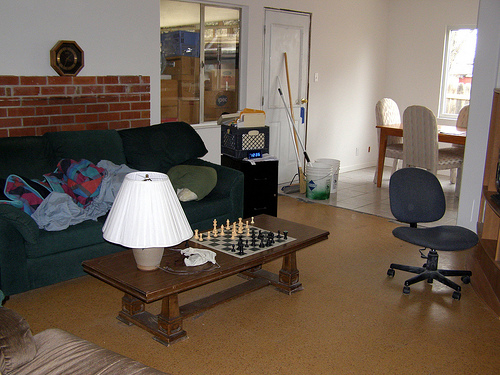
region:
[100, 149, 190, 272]
A lamp on the table.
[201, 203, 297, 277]
A chess game on the table.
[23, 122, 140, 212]
Clothes on the sofa.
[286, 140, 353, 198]
Buckets on the dining room floor.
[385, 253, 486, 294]
The chair has wheels.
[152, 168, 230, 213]
A pillow on the sofa.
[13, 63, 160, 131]
A brick wall behind the sofa.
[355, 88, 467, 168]
Chairs and table by the window.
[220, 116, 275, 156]
A milk crate sitting on top of a filing cabinet.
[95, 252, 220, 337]
The table is made of wood.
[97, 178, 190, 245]
a lamp shade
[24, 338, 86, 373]
the couch is brown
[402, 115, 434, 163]
a chair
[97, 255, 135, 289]
the table is brown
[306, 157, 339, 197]
two buckets on the floor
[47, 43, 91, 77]
a clock on the wall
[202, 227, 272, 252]
a game of chess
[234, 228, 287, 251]
black chess pieces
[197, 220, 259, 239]
white chess pieces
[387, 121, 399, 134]
the table is brown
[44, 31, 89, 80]
Octagon shaped clock resting on bricked area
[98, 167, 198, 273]
Table lamp with large white lamp shade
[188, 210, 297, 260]
Barely played game of chess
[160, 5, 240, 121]
Storage room full of cardboard boxes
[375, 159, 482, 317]
Grey/blue desk chair with wheels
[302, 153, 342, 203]
Large white buckets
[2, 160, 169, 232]
Red, blue, and black patchwork quilt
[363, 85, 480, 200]
Dining room table and chairs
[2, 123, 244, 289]
Comfy green sofa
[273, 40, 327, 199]
Cleaning supplies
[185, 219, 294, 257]
chess board and pieces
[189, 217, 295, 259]
chess board and pieces set up on a wooden table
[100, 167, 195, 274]
small lamp on coffee table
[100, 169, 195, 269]
tan lamp with white shade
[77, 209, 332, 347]
large wooden coffee table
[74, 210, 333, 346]
coffee table with small lamp and chess board on top of it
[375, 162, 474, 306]
rolling office chair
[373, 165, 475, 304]
dark grey rolling office chair+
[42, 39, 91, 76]
clock sitting on top of brick wall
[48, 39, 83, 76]
octagon shaped gold and black clock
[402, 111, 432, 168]
white chair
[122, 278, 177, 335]
the table is brown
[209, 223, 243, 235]
white chess pieces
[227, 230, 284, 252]
black chess pieces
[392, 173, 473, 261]
a chair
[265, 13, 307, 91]
a white door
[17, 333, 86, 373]
a brown couch